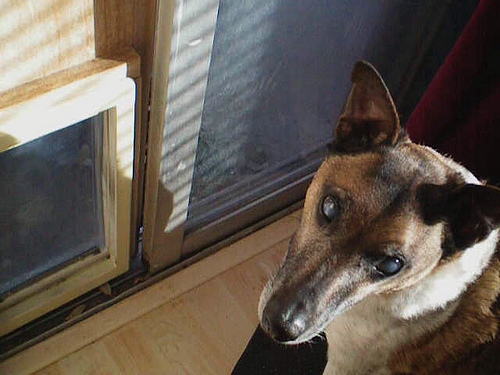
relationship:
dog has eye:
[256, 60, 498, 372] [375, 260, 408, 273]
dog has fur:
[256, 60, 498, 372] [420, 311, 443, 332]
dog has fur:
[256, 60, 498, 372] [353, 294, 416, 354]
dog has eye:
[256, 60, 498, 372] [376, 253, 406, 275]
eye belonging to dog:
[316, 185, 346, 232] [256, 60, 498, 372]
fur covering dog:
[252, 58, 484, 373] [256, 60, 498, 372]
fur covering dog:
[252, 58, 484, 373] [224, 56, 488, 356]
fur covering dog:
[252, 58, 484, 373] [216, 115, 498, 365]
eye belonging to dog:
[316, 185, 344, 224] [256, 60, 498, 372]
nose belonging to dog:
[256, 311, 305, 342] [252, 279, 329, 349]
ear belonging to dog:
[332, 59, 400, 148] [221, 54, 497, 374]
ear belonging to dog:
[339, 55, 391, 137] [256, 60, 499, 374]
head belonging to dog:
[256, 57, 499, 346] [256, 60, 498, 372]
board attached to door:
[46, 58, 178, 293] [141, 1, 374, 281]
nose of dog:
[256, 288, 338, 355] [265, 276, 321, 361]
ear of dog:
[453, 179, 499, 246] [401, 198, 484, 284]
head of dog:
[221, 257, 378, 375] [260, 65, 467, 357]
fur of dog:
[406, 239, 499, 333] [401, 258, 461, 349]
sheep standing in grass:
[129, 207, 225, 266] [192, 158, 204, 173]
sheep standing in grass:
[121, 278, 200, 361] [134, 304, 219, 375]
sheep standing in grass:
[130, 313, 217, 375] [121, 346, 172, 375]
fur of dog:
[406, 239, 499, 333] [342, 297, 454, 368]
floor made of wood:
[30, 235, 297, 373] [153, 295, 263, 375]